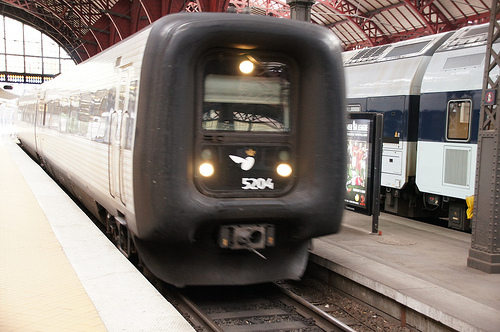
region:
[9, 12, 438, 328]
passenger train on tracks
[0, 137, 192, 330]
platform next to tracks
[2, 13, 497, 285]
two passenger trains in station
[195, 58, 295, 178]
three glowing white lights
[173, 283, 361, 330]
two metal rails of tracks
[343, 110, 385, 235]
sign on black post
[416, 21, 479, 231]
window on train car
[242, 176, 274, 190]
white number on black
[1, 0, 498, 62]
curved roof of train station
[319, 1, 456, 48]
red metal roof frame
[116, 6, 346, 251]
this is a train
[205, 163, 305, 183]
the lights are on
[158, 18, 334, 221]
the front is square like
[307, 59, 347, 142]
the front is black in color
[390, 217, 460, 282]
this is a pavement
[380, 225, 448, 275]
the pavement is cemented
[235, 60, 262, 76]
the light is bright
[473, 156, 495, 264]
this is a post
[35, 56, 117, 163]
the train is long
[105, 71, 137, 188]
the doors are closed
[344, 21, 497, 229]
two cars of train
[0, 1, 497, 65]
red and white domed roof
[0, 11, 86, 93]
daylight through arched window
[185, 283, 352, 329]
metal rails of train tracks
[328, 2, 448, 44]
red curved ceiling frames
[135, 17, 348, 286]
back of passenger train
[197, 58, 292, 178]
three circular white lights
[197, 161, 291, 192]
number under two lights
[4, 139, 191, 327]
white edge of platform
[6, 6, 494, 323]
passenger trains inside a station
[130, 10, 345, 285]
thick black border around front of train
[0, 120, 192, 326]
pink platform with white border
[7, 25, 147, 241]
shiny silver train cars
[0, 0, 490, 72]
ribbed and curved red station ceiling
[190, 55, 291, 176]
three bright white lights on train front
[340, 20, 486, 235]
black and white train on next track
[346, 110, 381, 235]
colorful poster in black frame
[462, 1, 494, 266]
solid and openwork gray support beam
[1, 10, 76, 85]
light coming through station side wall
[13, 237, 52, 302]
Sidewalk at train station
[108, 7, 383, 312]
Train at train station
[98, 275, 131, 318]
concrete curb at train station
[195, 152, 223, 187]
right headlight on a train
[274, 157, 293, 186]
left headlight on a train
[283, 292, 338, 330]
metal and wood train track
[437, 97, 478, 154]
side window on a train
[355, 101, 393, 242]
sign at train station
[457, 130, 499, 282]
metal support at train station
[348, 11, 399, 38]
White and red roof at train station